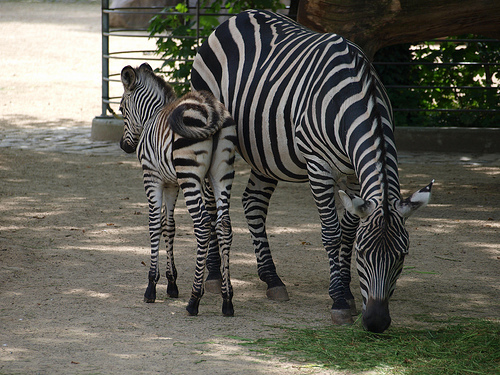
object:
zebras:
[186, 5, 436, 331]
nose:
[362, 298, 390, 324]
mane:
[356, 50, 392, 214]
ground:
[0, 1, 497, 375]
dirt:
[0, 115, 500, 373]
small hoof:
[222, 297, 235, 317]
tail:
[168, 91, 224, 140]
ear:
[396, 179, 435, 218]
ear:
[337, 189, 373, 217]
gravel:
[10, 155, 105, 363]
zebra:
[104, 62, 232, 324]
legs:
[142, 174, 165, 303]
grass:
[253, 319, 499, 374]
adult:
[189, 9, 435, 333]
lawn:
[256, 328, 466, 374]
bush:
[399, 39, 498, 114]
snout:
[120, 132, 129, 149]